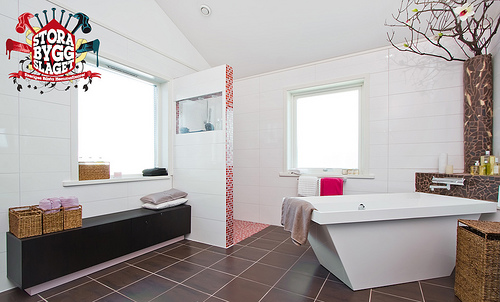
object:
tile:
[155, 259, 202, 283]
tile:
[180, 267, 235, 295]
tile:
[207, 255, 253, 277]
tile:
[235, 262, 289, 286]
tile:
[212, 276, 272, 302]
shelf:
[7, 199, 191, 234]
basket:
[7, 205, 43, 239]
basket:
[41, 209, 64, 235]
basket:
[61, 207, 84, 231]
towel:
[320, 177, 344, 196]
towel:
[298, 176, 320, 197]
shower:
[167, 64, 270, 247]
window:
[173, 91, 222, 134]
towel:
[280, 196, 316, 247]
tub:
[281, 189, 500, 291]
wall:
[234, 30, 488, 223]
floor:
[0, 219, 500, 302]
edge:
[317, 203, 496, 225]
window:
[295, 89, 360, 170]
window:
[73, 54, 158, 180]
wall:
[2, 53, 172, 289]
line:
[122, 260, 229, 301]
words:
[33, 29, 75, 46]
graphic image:
[7, 7, 101, 95]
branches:
[393, 17, 441, 46]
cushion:
[140, 188, 188, 205]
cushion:
[141, 199, 187, 211]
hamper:
[453, 219, 499, 301]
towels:
[142, 168, 168, 177]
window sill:
[62, 175, 171, 188]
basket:
[78, 165, 111, 180]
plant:
[382, 0, 500, 61]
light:
[200, 5, 212, 15]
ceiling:
[153, 1, 499, 80]